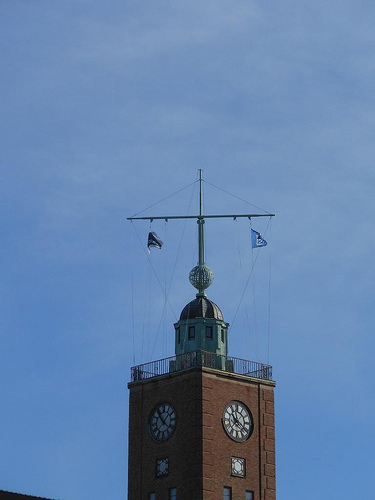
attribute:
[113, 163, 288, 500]
tower — tall, old, brick, large, brown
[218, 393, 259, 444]
clock — white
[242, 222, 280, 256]
flag — blue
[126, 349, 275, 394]
railing — metal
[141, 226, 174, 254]
flag — black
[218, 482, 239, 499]
window — square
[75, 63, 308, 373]
sky — blue, clear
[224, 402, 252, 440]
numbers — roman, black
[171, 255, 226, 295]
circle — metal